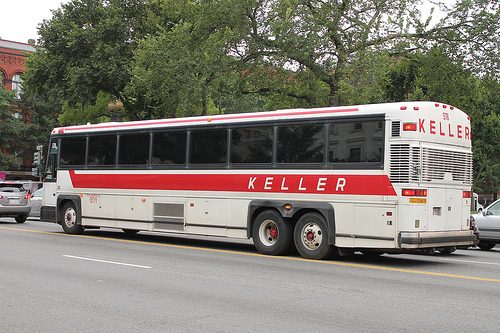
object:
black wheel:
[252, 209, 293, 255]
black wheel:
[293, 212, 332, 259]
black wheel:
[60, 202, 84, 235]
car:
[0, 180, 32, 224]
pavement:
[0, 220, 499, 331]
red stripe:
[65, 174, 397, 196]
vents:
[390, 143, 475, 183]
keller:
[419, 118, 471, 139]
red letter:
[429, 120, 436, 134]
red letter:
[439, 122, 446, 135]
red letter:
[448, 124, 454, 137]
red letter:
[457, 125, 463, 139]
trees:
[324, 0, 496, 110]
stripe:
[63, 105, 360, 133]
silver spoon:
[29, 90, 487, 260]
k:
[419, 118, 426, 133]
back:
[404, 100, 472, 254]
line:
[25, 228, 495, 283]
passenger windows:
[56, 114, 385, 168]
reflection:
[230, 115, 385, 164]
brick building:
[0, 38, 48, 166]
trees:
[23, 1, 260, 113]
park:
[0, 0, 500, 195]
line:
[64, 254, 152, 270]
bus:
[41, 100, 480, 260]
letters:
[418, 118, 470, 139]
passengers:
[63, 144, 383, 164]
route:
[4, 223, 483, 333]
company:
[248, 176, 347, 191]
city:
[0, 0, 500, 333]